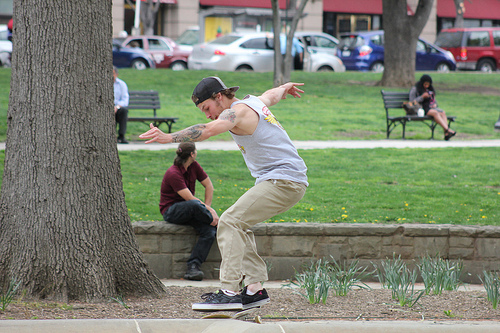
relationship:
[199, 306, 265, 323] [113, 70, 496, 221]
skateboard in park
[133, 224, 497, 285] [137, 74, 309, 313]
wall behind skater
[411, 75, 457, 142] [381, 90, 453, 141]
woman on bench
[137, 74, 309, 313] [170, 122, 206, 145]
skater has tattoo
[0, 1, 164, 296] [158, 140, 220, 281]
tree next to person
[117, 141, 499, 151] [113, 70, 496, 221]
path in park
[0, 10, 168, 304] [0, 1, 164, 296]
trunk of tree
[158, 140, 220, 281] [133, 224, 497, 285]
person on wall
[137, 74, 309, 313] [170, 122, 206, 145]
skater has a tattoo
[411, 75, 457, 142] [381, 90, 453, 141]
woman sitting on bench